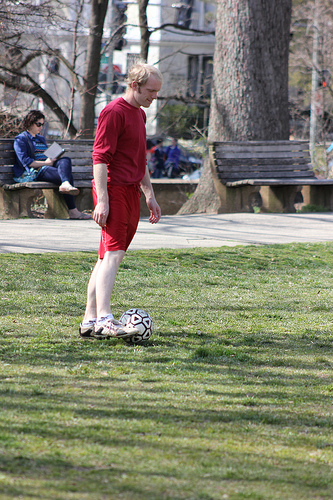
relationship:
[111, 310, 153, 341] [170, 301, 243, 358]
ball on ground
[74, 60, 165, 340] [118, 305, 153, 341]
man behind ball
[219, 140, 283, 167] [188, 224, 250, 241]
bench over sidewalk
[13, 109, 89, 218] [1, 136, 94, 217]
woman sitting on bench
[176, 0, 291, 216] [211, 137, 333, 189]
tree behind bench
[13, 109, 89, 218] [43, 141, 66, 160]
woman reading book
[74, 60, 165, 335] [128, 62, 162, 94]
man has hair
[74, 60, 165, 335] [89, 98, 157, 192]
man wearing man's shirt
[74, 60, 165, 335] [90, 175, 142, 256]
man wearing shorts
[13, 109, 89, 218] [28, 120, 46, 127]
woman wearing sunglasses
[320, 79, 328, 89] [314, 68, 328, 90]
light on stop light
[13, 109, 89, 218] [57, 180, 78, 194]
woman has foot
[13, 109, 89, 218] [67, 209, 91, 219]
woman has foot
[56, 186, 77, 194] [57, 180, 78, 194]
sandal on foot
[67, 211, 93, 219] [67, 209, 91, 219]
sandal on foot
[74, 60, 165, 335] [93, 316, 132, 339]
man wearing shoe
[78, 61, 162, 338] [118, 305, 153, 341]
player kicking ball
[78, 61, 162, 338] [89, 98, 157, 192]
player wearing man's shirt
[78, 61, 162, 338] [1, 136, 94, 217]
player standing near bench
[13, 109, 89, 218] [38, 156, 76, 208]
woman wearing jeans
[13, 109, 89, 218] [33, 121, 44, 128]
woman wearing sunglasses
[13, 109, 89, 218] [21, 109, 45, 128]
woman has hair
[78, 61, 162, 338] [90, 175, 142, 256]
player wearing shorts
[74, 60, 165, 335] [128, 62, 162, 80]
man has hair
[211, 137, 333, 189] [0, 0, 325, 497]
bench in a park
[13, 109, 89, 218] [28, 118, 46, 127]
woman wearing sunglasses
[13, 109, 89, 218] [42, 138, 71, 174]
woman reading a book